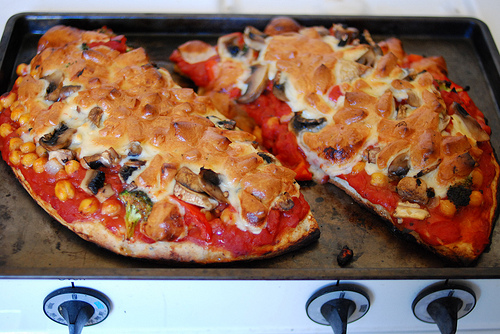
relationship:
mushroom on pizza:
[137, 199, 189, 241] [1, 19, 325, 268]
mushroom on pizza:
[78, 165, 109, 198] [1, 19, 325, 268]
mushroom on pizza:
[36, 122, 83, 153] [1, 19, 325, 268]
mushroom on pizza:
[197, 162, 233, 206] [1, 19, 325, 268]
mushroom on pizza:
[42, 69, 68, 103] [1, 19, 325, 268]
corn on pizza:
[78, 195, 101, 215] [1, 19, 325, 268]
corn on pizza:
[52, 175, 77, 204] [1, 19, 325, 268]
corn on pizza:
[62, 157, 82, 177] [1, 19, 325, 268]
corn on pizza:
[31, 154, 50, 174] [1, 19, 325, 268]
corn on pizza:
[0, 120, 17, 141] [1, 19, 325, 268]